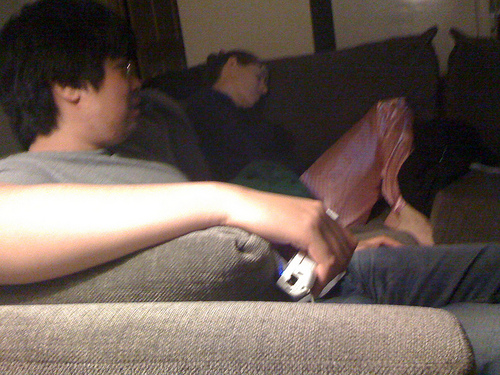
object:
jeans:
[313, 241, 498, 374]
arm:
[0, 156, 224, 284]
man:
[0, 0, 500, 374]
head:
[0, 0, 142, 147]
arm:
[0, 299, 473, 373]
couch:
[0, 25, 473, 373]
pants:
[298, 95, 413, 230]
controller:
[276, 208, 341, 302]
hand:
[230, 186, 357, 297]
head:
[201, 48, 271, 109]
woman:
[180, 48, 440, 246]